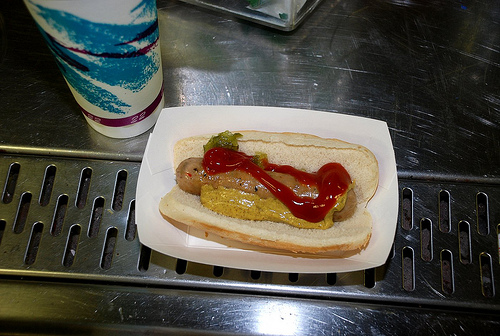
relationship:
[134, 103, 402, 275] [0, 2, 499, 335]
carton on counter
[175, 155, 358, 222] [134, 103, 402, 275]
hotdog in carton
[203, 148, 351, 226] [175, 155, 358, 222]
ketchup on hotdog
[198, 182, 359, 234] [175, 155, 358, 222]
mustard on hotdog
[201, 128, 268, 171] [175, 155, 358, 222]
relish on hotdog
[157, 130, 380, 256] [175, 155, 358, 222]
bun under hotdog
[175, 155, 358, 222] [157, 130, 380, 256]
hotdog on bun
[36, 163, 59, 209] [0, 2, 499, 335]
hole in counter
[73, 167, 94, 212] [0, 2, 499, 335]
hole in counter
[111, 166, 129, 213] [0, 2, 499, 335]
hole in counter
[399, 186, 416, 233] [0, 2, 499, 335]
hole in counter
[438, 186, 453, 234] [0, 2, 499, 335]
hole in counter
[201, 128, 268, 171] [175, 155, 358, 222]
relish on top of hotdog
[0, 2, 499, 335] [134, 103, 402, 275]
counter under carton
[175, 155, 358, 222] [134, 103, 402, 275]
hotdog on carton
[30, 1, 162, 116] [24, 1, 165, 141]
design on cup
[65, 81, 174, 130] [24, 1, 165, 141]
stripe on cup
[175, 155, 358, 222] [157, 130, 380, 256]
hotdog in bun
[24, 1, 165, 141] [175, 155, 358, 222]
cup next to hotdog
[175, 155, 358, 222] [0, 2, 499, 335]
hotdog on top of counter